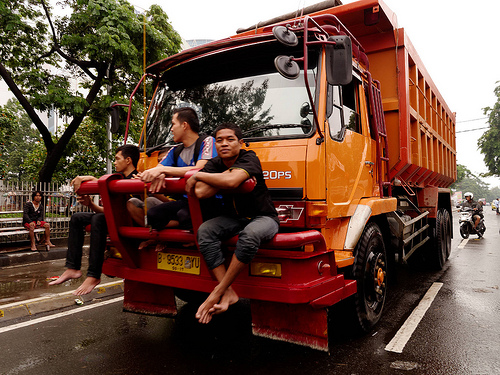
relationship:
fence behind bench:
[2, 177, 78, 251] [1, 214, 77, 255]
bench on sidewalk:
[1, 214, 77, 255] [6, 252, 118, 304]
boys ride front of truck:
[186, 124, 280, 326] [68, 1, 458, 357]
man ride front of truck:
[128, 102, 224, 247] [68, 1, 458, 357]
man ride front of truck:
[45, 143, 147, 295] [68, 1, 458, 357]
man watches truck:
[22, 189, 57, 251] [68, 1, 458, 357]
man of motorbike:
[458, 190, 484, 230] [456, 204, 484, 239]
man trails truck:
[458, 190, 484, 230] [68, 1, 458, 357]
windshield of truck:
[138, 39, 327, 153] [68, 1, 458, 357]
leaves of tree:
[72, 5, 129, 56] [0, 2, 189, 215]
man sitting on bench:
[22, 189, 57, 251] [1, 224, 51, 246]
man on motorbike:
[458, 190, 484, 230] [456, 204, 486, 239]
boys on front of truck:
[186, 124, 280, 326] [68, 1, 458, 357]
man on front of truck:
[141, 106, 217, 232] [68, 1, 458, 357]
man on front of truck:
[44, 139, 151, 301] [68, 1, 458, 357]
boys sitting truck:
[66, 112, 288, 322] [68, 1, 458, 357]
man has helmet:
[459, 190, 484, 225] [459, 188, 477, 204]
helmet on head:
[459, 188, 477, 204] [457, 190, 480, 207]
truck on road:
[68, 1, 458, 357] [0, 216, 496, 372]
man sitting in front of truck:
[45, 143, 147, 295] [68, 1, 458, 357]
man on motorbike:
[458, 190, 484, 230] [451, 205, 482, 236]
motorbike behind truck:
[451, 205, 482, 236] [68, 1, 458, 357]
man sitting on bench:
[14, 184, 76, 259] [0, 226, 53, 252]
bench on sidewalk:
[0, 226, 53, 252] [3, 243, 134, 325]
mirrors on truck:
[263, 10, 361, 98] [68, 1, 458, 357]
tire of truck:
[345, 211, 411, 337] [68, 1, 458, 357]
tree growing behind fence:
[0, 2, 189, 215] [0, 181, 99, 244]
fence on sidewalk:
[0, 181, 99, 244] [1, 235, 133, 332]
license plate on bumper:
[156, 252, 201, 276] [100, 230, 346, 305]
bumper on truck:
[100, 230, 346, 305] [68, 1, 458, 357]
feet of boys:
[194, 281, 237, 325] [186, 124, 280, 326]